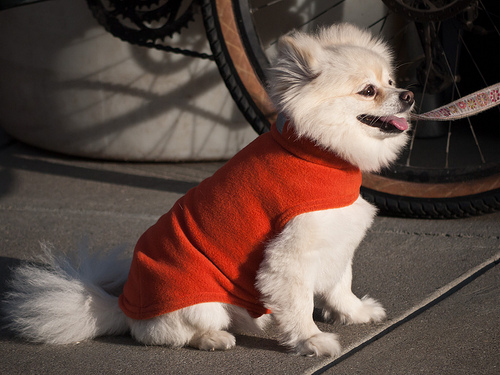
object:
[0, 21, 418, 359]
dog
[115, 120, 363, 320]
sweater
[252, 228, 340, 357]
legs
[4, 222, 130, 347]
dog tail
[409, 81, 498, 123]
leash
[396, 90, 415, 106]
nose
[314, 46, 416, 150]
dog face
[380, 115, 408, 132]
tongue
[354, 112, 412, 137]
dog mouth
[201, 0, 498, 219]
tire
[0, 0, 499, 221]
bike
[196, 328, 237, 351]
right paw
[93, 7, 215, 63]
chain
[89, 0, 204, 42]
sprocket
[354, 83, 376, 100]
dogs eye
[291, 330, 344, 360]
dogs paw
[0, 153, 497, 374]
floor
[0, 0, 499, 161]
distance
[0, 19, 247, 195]
shadow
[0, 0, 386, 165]
building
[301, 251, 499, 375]
groove